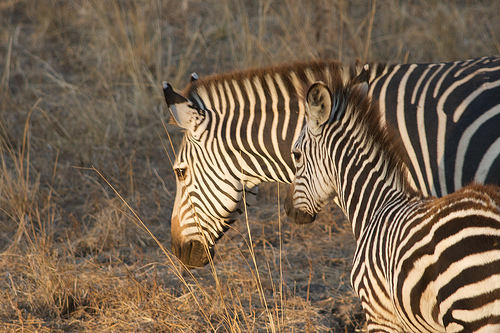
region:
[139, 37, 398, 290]
There are two zebras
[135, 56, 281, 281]
This is an older zebra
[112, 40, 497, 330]
The zebras are striped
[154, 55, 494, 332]
The zebras are black and white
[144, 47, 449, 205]
The zebras have a striped mane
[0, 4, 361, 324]
The grass is dry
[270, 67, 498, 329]
Baby zebra in the front.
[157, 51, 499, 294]
Adult zebra behind baby.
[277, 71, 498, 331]
Black and white stripes on zebra.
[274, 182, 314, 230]
Black nose on the zebra.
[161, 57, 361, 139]
Black and white mane on zebra.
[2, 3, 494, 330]
Brown grass covering the ground.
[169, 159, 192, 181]
Black eye on the zebra.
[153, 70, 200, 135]
Black and white ear on the zebra.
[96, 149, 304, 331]
Long brown weeds on the ground.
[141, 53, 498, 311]
Two zebras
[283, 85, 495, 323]
This zebra is the smaller of the two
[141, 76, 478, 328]
You can only see the left side of the zebras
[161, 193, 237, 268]
Sun shining on the zebra's face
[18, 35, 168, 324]
Ground covered in brown grass and hay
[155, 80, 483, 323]
Both zebras are standing in place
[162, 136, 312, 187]
Both zebras' eyes are open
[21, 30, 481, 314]
The picture is taken outside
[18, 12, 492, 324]
The picture is taken during daylight hours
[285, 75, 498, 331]
a baby zebra looking to the left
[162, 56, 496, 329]
an adult zebra behind a baby zebra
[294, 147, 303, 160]
the dark left eye of a baby zebra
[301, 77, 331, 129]
the left ear of a baby zebra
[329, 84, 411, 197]
the striped mane of a baby zebra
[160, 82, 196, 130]
the black and white left ear of an adult zebra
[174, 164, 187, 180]
the left dark eye of an adult zebra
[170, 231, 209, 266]
the black snout and mouth of a zebra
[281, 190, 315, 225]
the black snout and mouth of a baby zebra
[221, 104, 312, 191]
the black and white striped neck of an adult zebra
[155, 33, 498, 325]
a mother and baby zebra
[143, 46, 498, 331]
a couple of zebars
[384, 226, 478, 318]
black and white strips on a zebra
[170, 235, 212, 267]
a black nose on a zebra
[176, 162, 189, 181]
a left eye on a zebra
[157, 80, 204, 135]
a left ear on a zebra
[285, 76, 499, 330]
a baby zebra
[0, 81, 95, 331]
died brown grass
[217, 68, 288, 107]
the mane on a zebar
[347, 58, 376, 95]
a right ear on a zebra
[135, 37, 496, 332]
two zebras in the grass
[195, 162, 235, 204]
black stripe on zebra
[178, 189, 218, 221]
black stripe on zebra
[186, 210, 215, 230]
black stripe on zebra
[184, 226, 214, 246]
black stripe on zebra